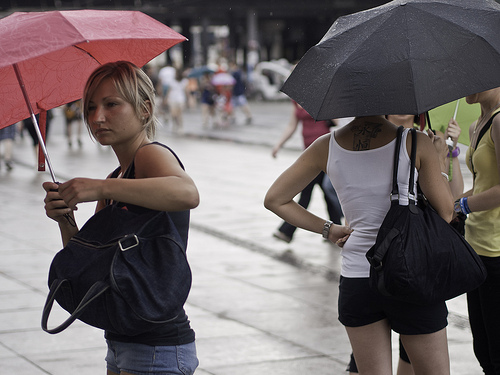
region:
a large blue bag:
[23, 142, 193, 338]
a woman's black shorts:
[331, 275, 438, 335]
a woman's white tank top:
[321, 130, 412, 286]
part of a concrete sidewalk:
[180, 112, 346, 372]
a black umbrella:
[279, 0, 499, 148]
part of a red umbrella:
[0, 1, 203, 153]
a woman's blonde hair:
[81, 63, 158, 145]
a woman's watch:
[319, 218, 339, 244]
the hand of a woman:
[52, 175, 114, 202]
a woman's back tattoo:
[339, 115, 389, 151]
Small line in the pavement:
[17, 343, 57, 374]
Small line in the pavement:
[295, 336, 343, 374]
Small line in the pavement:
[199, 358, 209, 373]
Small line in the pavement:
[203, 348, 315, 368]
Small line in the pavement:
[223, 314, 257, 332]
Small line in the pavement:
[268, 289, 318, 321]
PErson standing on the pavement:
[51, 77, 229, 372]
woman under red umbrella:
[44, 62, 201, 374]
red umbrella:
[2, 10, 185, 217]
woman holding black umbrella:
[263, 113, 456, 373]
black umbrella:
[280, 0, 498, 129]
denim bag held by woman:
[36, 143, 190, 331]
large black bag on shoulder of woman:
[366, 125, 486, 296]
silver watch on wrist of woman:
[322, 217, 332, 239]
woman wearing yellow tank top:
[460, 85, 498, 372]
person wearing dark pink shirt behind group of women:
[270, 93, 345, 243]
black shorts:
[335, 275, 447, 336]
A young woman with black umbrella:
[263, 115, 453, 374]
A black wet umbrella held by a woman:
[278, 0, 498, 122]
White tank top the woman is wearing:
[325, 128, 418, 278]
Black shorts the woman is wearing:
[337, 275, 447, 332]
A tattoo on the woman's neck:
[348, 118, 380, 150]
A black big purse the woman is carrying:
[365, 126, 486, 307]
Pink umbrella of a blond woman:
[0, 9, 189, 128]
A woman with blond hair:
[43, 60, 196, 372]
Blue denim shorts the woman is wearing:
[104, 340, 198, 373]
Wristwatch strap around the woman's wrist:
[322, 220, 329, 237]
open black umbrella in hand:
[293, 7, 462, 107]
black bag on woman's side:
[41, 195, 181, 352]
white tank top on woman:
[320, 105, 424, 286]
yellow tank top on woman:
[450, 113, 498, 250]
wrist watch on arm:
[320, 214, 331, 239]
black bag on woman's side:
[373, 156, 450, 307]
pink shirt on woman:
[285, 90, 327, 155]